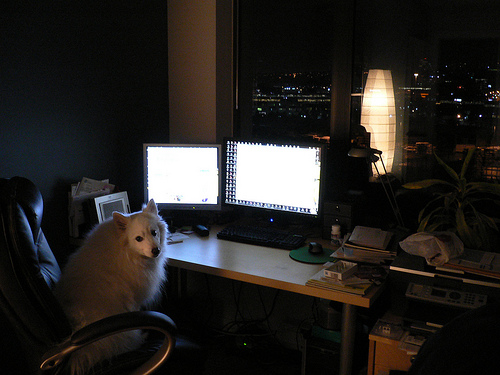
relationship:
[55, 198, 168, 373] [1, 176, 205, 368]
desk on chair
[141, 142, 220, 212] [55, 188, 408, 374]
monitor on desk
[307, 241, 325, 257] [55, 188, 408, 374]
mouse on desk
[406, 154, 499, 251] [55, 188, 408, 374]
plant near desk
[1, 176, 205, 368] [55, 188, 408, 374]
chair near desk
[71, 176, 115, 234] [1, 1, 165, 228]
paper near wall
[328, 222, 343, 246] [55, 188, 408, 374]
bottle on desk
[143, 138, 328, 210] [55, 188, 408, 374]
monitors on desk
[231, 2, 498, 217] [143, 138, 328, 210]
window behind monitors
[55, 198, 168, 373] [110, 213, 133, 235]
desk has ear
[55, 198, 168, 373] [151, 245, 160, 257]
desk has nose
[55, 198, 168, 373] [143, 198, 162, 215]
desk has ear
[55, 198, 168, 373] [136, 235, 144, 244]
desk has eye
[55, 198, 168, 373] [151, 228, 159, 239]
desk has eye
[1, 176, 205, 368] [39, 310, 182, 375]
chair has arm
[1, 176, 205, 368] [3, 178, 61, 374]
chair has back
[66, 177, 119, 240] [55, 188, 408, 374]
papers near desk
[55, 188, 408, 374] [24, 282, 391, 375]
desk has frame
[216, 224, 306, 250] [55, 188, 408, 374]
keyboard on desk